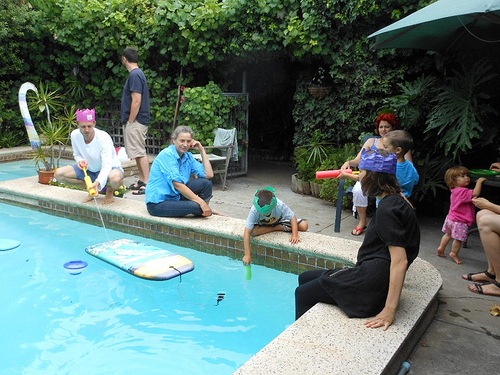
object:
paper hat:
[76, 108, 95, 122]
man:
[119, 47, 152, 195]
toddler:
[437, 166, 485, 265]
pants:
[147, 178, 213, 217]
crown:
[253, 186, 279, 215]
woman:
[462, 196, 500, 299]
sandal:
[462, 269, 497, 283]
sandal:
[468, 280, 499, 296]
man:
[144, 125, 225, 220]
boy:
[375, 130, 421, 210]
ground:
[392, 105, 437, 132]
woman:
[293, 144, 420, 331]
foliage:
[143, 43, 149, 50]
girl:
[437, 167, 487, 265]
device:
[63, 260, 88, 276]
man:
[53, 109, 125, 205]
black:
[296, 194, 420, 321]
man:
[293, 144, 422, 331]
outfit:
[446, 187, 475, 225]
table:
[462, 175, 500, 249]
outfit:
[318, 194, 421, 319]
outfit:
[70, 128, 122, 191]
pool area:
[1, 138, 484, 373]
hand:
[242, 255, 253, 266]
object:
[315, 169, 360, 179]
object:
[84, 238, 195, 282]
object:
[0, 241, 21, 253]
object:
[246, 264, 253, 281]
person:
[340, 113, 412, 236]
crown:
[359, 148, 398, 175]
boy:
[241, 187, 308, 268]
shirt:
[144, 144, 206, 204]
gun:
[82, 167, 96, 196]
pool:
[1, 144, 441, 373]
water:
[0, 155, 307, 373]